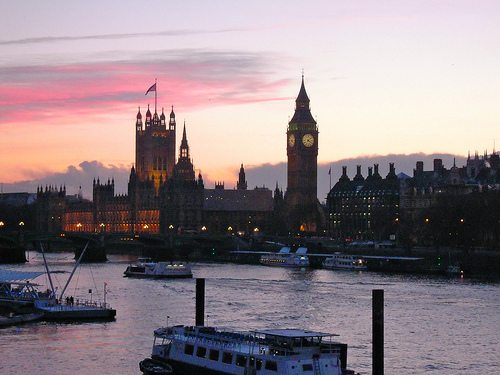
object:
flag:
[145, 83, 157, 96]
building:
[128, 77, 177, 201]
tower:
[285, 68, 319, 207]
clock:
[302, 133, 315, 147]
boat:
[123, 258, 193, 280]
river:
[0, 251, 500, 375]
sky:
[1, 0, 500, 205]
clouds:
[1, 25, 467, 191]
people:
[65, 296, 74, 308]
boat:
[34, 281, 117, 323]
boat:
[139, 278, 385, 375]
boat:
[322, 252, 367, 271]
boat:
[259, 252, 310, 267]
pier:
[228, 250, 426, 274]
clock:
[288, 134, 296, 148]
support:
[74, 239, 110, 264]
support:
[0, 246, 29, 265]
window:
[152, 156, 162, 171]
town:
[1, 66, 500, 282]